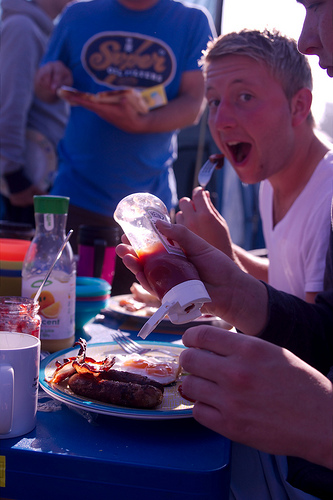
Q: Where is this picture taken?
A: A restaurant.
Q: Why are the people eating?
A: They are hungry.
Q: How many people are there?
A: Four.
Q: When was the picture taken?
A: At daytime.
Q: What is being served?
A: Sausages.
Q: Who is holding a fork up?
A: The blond man.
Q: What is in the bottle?
A: Orange juice.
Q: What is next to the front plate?
A: A cup.